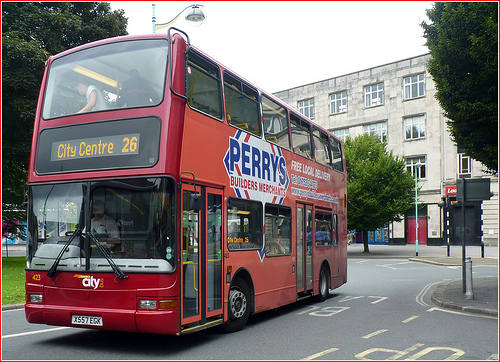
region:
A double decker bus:
[19, 26, 294, 340]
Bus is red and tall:
[13, 24, 351, 334]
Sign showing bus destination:
[40, 120, 155, 167]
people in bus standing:
[53, 61, 158, 112]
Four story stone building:
[328, 54, 425, 131]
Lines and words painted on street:
[353, 289, 443, 358]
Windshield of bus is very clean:
[27, 175, 172, 275]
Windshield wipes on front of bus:
[51, 213, 126, 282]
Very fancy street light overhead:
[150, 0, 210, 35]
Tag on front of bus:
[65, 308, 115, 333]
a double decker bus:
[14, 30, 398, 317]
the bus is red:
[19, 26, 372, 326]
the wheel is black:
[210, 266, 263, 333]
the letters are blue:
[225, 137, 315, 191]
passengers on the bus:
[45, 61, 295, 123]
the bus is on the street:
[13, 12, 387, 347]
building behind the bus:
[238, 50, 488, 284]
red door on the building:
[392, 200, 430, 248]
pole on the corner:
[450, 166, 477, 299]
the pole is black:
[452, 167, 472, 289]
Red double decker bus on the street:
[26, 32, 353, 330]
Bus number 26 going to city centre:
[47, 135, 156, 159]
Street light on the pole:
[146, 2, 211, 28]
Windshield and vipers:
[28, 180, 179, 284]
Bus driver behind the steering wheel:
[55, 187, 122, 262]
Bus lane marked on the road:
[242, 265, 407, 355]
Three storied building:
[338, 60, 449, 251]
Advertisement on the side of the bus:
[216, 114, 351, 219]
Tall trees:
[0, 4, 123, 94]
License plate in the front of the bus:
[68, 307, 113, 329]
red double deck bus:
[19, 35, 349, 337]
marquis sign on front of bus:
[48, 134, 147, 159]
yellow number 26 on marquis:
[117, 135, 142, 151]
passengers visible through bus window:
[54, 66, 157, 114]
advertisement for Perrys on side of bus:
[215, 128, 346, 208]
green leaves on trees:
[335, 127, 424, 234]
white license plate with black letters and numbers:
[65, 311, 104, 327]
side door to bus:
[285, 193, 320, 300]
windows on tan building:
[281, 67, 430, 124]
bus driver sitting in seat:
[75, 198, 126, 255]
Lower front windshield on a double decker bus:
[23, 172, 179, 274]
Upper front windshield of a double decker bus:
[37, 36, 178, 121]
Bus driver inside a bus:
[65, 195, 132, 258]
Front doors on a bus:
[175, 175, 230, 339]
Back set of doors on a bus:
[290, 194, 325, 300]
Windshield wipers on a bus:
[41, 224, 128, 281]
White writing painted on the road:
[330, 321, 457, 358]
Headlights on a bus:
[22, 285, 179, 315]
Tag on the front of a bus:
[63, 307, 108, 329]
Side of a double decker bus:
[180, 42, 350, 340]